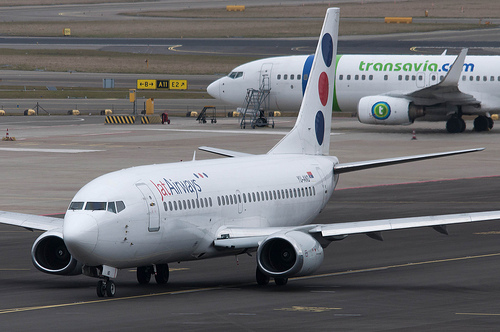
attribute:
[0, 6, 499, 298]
airplane — driving, white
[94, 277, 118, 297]
gear — landing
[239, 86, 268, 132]
ladder — metal, stairs, portable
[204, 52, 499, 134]
plane — white, green, blue, grounded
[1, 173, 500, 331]
runway — black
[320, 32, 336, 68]
dot — blue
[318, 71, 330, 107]
dot — red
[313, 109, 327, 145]
dot — blue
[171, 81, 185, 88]
marking — black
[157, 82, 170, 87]
marking — yellow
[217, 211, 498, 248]
wing — white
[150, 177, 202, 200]
writing — red, blue, name, jat airways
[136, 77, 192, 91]
sign — yellow, black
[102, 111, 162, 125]
barrier — yellow, black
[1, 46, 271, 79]
ground — brown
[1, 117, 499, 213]
tarmac — grey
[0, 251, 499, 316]
line — white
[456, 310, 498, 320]
line — white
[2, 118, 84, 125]
line — white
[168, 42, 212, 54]
line — white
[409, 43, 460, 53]
line — white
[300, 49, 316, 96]
stripe — blue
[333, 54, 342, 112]
stripe — green